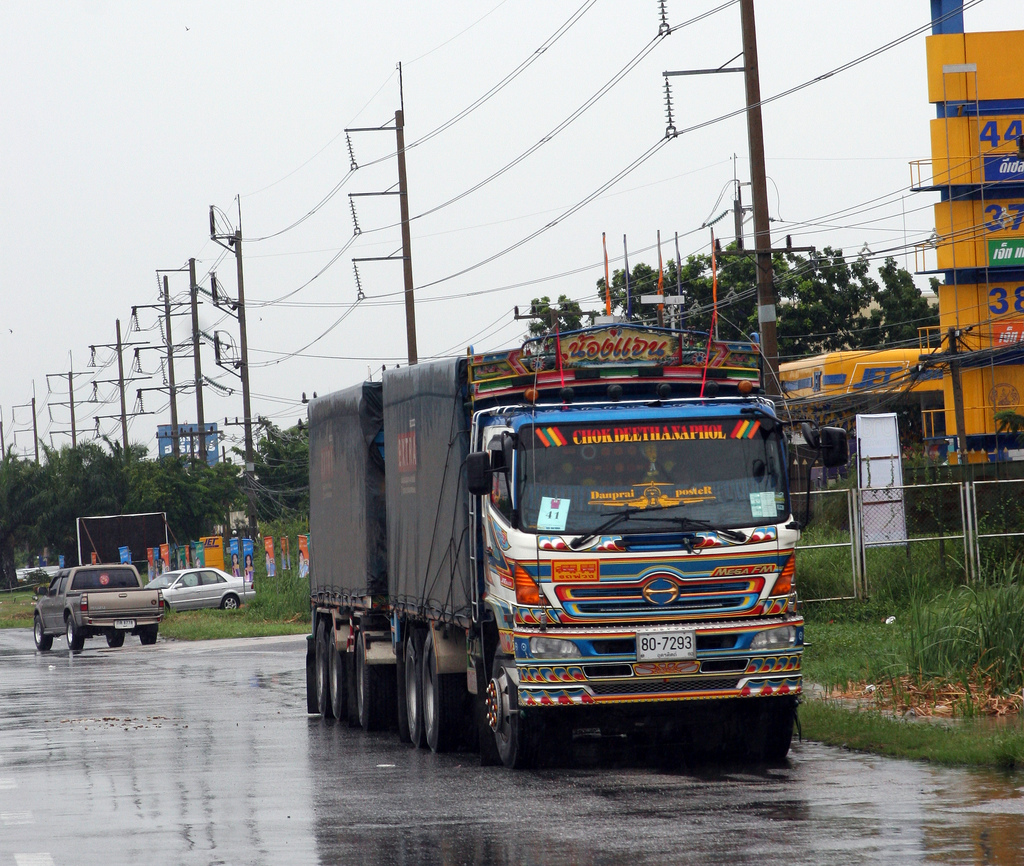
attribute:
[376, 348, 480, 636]
tarp — black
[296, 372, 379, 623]
tarp — black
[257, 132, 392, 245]
wire — electric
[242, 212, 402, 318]
wire — electric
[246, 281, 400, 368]
wire — electric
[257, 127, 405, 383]
wires — electric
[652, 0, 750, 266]
wires — electric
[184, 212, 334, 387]
wires — electric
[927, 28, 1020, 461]
sign — orange, blue, price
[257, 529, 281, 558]
flag — orange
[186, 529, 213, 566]
flag — blue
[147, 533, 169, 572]
flag — orange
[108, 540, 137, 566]
flag — blue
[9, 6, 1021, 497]
sky — hazy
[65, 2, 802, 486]
poles — wooden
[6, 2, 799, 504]
poles — wooden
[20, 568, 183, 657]
truck — tan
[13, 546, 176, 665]
truck — tan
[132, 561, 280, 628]
vehicle — silver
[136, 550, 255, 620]
vehicle — silver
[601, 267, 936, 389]
leaves — green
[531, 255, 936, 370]
leaves — green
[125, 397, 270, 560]
leaves — green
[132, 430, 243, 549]
leaves — green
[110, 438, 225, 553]
leaves — green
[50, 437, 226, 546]
leaves — green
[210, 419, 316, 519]
leaves — green